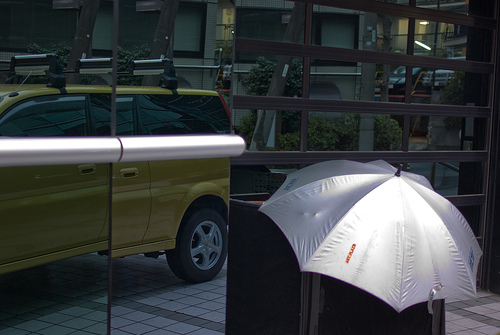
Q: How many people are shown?
A: None.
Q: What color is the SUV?
A: Yellow.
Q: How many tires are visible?
A: One.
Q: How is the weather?
A: Sunny.